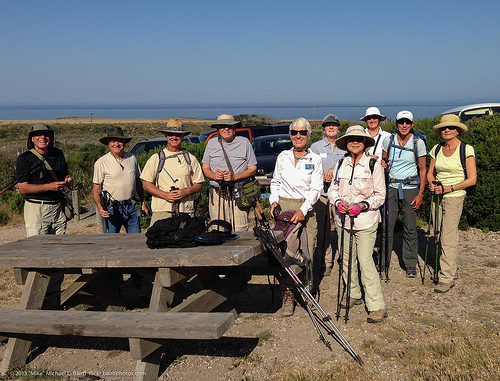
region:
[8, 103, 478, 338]
a group of people posing together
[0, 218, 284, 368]
a wooden outdoor table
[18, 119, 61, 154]
man wearing a hat with a flap at the back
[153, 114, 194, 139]
man wearing a straw hat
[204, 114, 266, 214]
strap of green bag slung across man's body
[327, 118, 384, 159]
woman wearing a white hat with a large brim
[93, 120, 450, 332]
several people are holding short poles with pointed ends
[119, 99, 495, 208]
vehicles parked behind group of people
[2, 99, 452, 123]
calm looking body of water in the distance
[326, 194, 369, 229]
woman wearing fingerless gloves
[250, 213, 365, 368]
Tripod leaning against a picnic table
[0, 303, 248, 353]
Seat on a picnic table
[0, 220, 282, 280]
Table top of a picnic table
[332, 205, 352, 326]
Poles used for hiking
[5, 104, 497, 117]
Large body of water in the background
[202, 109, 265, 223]
Man carrying a handbag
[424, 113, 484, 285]
Woman wearing a backpack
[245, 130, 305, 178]
Car parked in the background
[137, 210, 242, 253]
Backpack sitting on a picnic table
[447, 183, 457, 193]
Wristwatch worn by a woman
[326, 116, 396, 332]
a woman holding poles.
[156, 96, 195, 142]
a brown rimmed hat.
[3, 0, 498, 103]
crystal clear blue sky.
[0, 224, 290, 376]
a large wooden bench.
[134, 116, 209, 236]
a man with a backpack.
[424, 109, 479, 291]
a woman wearing a yellow shirt.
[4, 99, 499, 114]
A large body of water.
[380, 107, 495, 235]
a large green leafy bush.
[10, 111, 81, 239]
a man standing near a bench.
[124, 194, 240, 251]
a large black bag.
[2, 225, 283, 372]
Wooden camping bench/table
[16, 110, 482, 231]
Group of tourists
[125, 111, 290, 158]
Vehicles parked in the background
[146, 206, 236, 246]
Bag on the table top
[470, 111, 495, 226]
Bush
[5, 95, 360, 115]
Wide water mass in the background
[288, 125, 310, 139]
Man wearing shaded glasses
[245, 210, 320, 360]
Equipment leaning on the woodent table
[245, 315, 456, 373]
Loose gravel on the ground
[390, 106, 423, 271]
Person wearing a backpack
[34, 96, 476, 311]
people posing for picture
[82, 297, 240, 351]
wood bench of picnic table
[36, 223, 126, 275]
top of picnic table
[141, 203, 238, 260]
black bag on table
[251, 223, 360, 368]
poles leaning against table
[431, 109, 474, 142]
hat on woman's head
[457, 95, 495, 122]
roof of parked car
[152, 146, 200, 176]
staps on man's shoulder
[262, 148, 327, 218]
white long sleeved shirt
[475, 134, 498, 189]
green leaves on bush